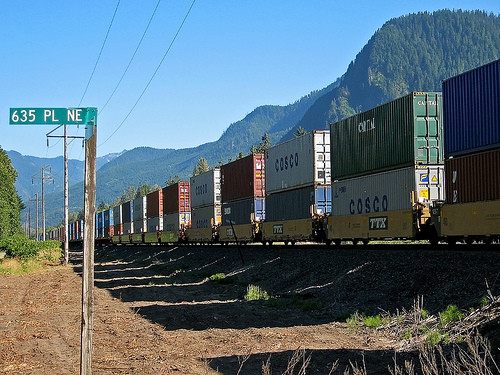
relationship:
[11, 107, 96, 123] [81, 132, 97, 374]
street sign on pole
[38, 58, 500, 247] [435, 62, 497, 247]
train with car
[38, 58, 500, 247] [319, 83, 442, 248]
train with car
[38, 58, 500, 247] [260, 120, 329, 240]
train with car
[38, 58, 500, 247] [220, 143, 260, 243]
train with car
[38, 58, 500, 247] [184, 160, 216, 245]
train with car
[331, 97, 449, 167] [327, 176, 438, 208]
rail car on top of rail car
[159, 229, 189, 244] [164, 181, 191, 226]
train car holding double unit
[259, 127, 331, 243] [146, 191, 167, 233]
train car holding double unit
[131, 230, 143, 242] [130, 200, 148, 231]
train car holding double unit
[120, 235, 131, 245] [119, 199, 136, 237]
train car holding double unit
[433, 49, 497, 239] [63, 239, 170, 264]
train car cast shadow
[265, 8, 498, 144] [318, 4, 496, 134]
mountain covered in trees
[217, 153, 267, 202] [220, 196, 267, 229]
train car on top of train car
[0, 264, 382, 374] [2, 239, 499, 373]
dirt on ground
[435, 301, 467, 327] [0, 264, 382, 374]
grass in dirt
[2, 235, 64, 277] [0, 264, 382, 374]
grass beside dirt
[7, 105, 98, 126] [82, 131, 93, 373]
street sign on pole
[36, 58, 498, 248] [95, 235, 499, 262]
train on tracks